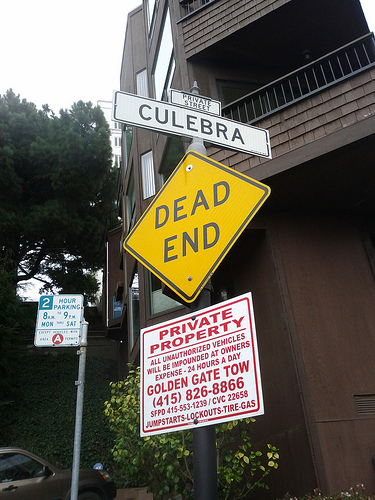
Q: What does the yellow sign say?
A: Dead end.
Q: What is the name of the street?
A: Culebra.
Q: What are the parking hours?
A: 8:00 am to 9:00 pm.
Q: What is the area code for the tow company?
A: 415.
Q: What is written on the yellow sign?
A: Dead End.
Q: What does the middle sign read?
A: Dead End.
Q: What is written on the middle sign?
A: Dead End.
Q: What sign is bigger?
A: The yellow sign.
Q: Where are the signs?
A: On a pole.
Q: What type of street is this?
A: A private street.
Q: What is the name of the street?
A: Culebra.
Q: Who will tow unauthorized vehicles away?
A: Golden Gate Tow.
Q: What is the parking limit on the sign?
A: 2 hours.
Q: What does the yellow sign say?
A: Dead End.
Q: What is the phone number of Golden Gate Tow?
A: 415-826-8866.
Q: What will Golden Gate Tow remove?
A: Unauthorized vehicles.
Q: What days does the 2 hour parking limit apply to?
A: Monday through Saturday.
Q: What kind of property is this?
A: Private property.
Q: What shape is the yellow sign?
A: Diamond-shape.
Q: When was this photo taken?
A: Daytime.